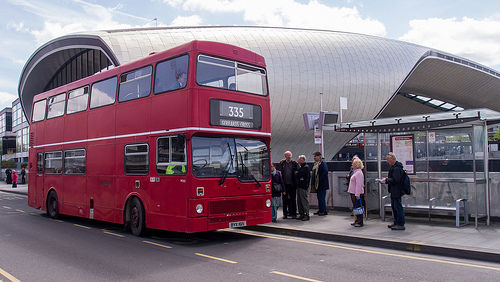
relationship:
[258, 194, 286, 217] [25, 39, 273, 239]
light on bus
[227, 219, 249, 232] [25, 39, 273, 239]
license plate on bus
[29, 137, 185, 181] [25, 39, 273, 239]
windows on bus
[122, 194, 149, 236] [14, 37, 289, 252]
tire on bus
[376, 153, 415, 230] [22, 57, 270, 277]
man waiting to board bus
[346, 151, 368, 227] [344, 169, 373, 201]
person wearing jacket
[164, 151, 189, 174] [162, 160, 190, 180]
bus driver wearing jacket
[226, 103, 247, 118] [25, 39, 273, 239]
number 335 on bus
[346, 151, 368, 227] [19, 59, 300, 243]
person waiting for bus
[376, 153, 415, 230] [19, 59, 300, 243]
man waiting for bus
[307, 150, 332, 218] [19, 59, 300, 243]
people waiting for bus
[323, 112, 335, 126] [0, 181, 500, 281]
camera watching road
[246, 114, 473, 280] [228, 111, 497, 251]
people at bus station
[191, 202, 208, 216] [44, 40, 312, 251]
bus headlight on bus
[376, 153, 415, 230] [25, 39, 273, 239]
man waiting for bus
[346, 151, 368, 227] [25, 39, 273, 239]
person waiting for bus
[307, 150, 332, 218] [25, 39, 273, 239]
people waiting for bus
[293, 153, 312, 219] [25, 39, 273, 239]
person waiting for bus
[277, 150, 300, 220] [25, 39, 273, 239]
person waiting for bus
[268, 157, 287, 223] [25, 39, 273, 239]
person waiting for bus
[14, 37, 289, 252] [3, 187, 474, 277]
bus on road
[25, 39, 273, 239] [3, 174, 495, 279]
bus on road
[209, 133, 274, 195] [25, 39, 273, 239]
wipers on bus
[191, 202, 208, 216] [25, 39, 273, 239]
bus headlight on bus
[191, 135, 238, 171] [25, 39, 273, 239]
window is in front of bus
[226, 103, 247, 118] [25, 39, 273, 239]
number 335 on top of bus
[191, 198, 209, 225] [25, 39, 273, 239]
bus headlight in front of bus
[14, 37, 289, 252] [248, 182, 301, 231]
bus has headlight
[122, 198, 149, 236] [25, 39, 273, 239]
tire in front of bus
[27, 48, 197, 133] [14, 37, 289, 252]
windows are in bus